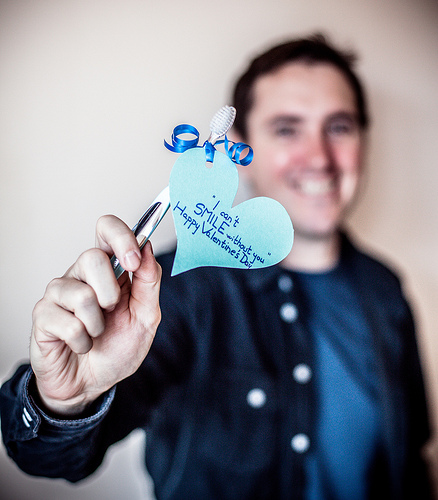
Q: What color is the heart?
A: Light blue.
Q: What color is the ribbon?
A: Dark blue.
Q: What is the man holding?
A: The toothbrush.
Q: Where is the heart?
A: Tied to the toothbrush.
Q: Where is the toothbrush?
A: In the man's hand.